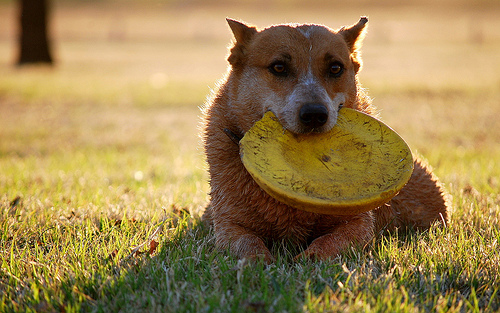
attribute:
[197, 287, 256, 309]
grass — green, short, yellow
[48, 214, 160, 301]
grass — yellow, green, short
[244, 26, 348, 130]
face — white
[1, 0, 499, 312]
grass — green, yellow, short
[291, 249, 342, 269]
paws — brown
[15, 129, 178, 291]
grass — green, short, yellow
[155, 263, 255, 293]
shadow — dark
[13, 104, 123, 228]
yellow grass — short, green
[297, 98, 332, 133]
nose — black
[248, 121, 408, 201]
frisbee — yellow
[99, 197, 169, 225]
grass — yellow, short, green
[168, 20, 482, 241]
dog — brown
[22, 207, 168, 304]
grass — short, green, yellow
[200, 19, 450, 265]
dog — green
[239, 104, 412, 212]
frisbee — yellow, dirty